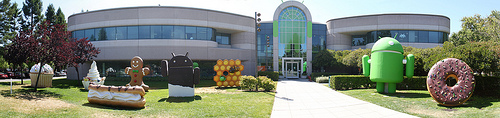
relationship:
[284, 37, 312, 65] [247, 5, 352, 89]
section of building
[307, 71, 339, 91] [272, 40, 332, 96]
boulder in front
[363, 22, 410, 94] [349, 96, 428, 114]
sculpture on lawn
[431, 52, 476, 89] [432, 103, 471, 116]
doughnut on ground